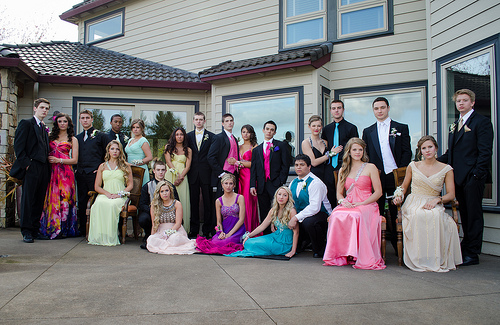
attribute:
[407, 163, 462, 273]
dress — formal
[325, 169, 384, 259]
dress — formal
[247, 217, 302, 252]
dress — formal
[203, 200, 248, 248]
dress — formal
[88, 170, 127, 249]
dress — formal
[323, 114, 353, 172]
blue tie — blue 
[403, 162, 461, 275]
dress — formal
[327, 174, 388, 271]
dress — formal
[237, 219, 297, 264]
dress — formal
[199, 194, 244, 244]
dress — formal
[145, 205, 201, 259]
dress — formal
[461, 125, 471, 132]
pocket square — yellow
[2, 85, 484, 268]
party — wedding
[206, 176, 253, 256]
dress — purple 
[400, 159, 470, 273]
dress — formal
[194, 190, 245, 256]
dress — purple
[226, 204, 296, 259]
dress — blue 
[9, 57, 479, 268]
teens — posing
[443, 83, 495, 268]
man — still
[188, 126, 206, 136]
tie — yellow , bow 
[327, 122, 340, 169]
tie — blue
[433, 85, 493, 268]
man — standing, young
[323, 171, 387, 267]
dress — pink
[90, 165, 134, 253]
dress — formal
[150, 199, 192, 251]
dress — formal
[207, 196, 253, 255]
dress — formal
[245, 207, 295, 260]
dress — formal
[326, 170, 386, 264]
dress — formal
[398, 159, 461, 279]
dress — formal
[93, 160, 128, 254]
dress — yellow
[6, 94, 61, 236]
man — young, standing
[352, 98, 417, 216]
man — still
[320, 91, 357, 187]
man — still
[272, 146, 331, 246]
man — still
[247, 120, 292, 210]
man — still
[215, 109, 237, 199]
man — still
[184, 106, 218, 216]
man — still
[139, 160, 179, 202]
man — still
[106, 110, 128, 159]
man — still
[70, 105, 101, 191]
man — still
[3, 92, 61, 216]
man — still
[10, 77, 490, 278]
party — wedding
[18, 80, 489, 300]
party — wedding